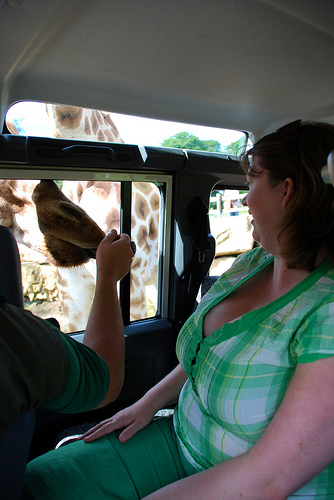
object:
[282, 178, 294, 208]
ear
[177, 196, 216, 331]
seat belt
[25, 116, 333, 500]
woman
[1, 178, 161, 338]
window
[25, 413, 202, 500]
green pants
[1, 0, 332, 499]
vehicle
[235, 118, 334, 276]
brown hair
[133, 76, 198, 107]
floor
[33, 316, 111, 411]
sleeve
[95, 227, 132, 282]
hand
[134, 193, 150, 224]
spots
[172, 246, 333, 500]
shirt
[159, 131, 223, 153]
tree top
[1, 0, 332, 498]
bus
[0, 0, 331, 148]
top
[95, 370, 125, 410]
elbow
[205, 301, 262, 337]
cleveage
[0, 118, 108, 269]
head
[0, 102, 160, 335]
giraffe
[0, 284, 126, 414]
arm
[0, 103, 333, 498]
passengers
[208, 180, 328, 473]
distance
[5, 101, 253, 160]
sunlight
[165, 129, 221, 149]
tops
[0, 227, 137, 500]
someone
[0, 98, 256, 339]
park